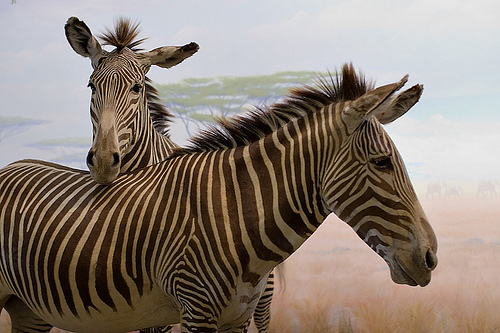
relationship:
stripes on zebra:
[206, 145, 271, 265] [6, 62, 469, 323]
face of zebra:
[323, 77, 443, 292] [6, 62, 469, 323]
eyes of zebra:
[82, 77, 162, 98] [51, 6, 199, 192]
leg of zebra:
[5, 290, 59, 332] [6, 62, 469, 323]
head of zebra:
[323, 77, 443, 292] [6, 62, 469, 323]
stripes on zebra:
[145, 121, 167, 158] [51, 6, 199, 192]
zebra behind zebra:
[51, 6, 199, 192] [6, 62, 469, 323]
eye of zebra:
[366, 152, 397, 173] [6, 62, 469, 323]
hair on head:
[332, 57, 381, 116] [323, 77, 443, 292]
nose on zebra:
[409, 230, 445, 276] [6, 62, 469, 323]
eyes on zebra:
[82, 77, 162, 98] [51, 6, 199, 192]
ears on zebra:
[351, 57, 428, 139] [6, 62, 469, 323]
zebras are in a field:
[7, 17, 442, 324] [309, 209, 494, 329]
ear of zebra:
[345, 73, 407, 129] [6, 62, 469, 323]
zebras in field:
[7, 17, 442, 324] [309, 209, 494, 329]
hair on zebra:
[332, 57, 381, 116] [6, 62, 469, 323]